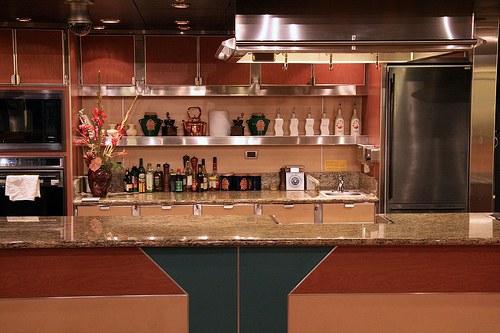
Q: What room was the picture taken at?
A: It was taken at the kitchen.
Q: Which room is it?
A: It is a kitchen.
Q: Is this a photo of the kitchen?
A: Yes, it is showing the kitchen.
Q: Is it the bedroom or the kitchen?
A: It is the kitchen.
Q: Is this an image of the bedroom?
A: No, the picture is showing the kitchen.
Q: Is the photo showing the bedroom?
A: No, the picture is showing the kitchen.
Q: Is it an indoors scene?
A: Yes, it is indoors.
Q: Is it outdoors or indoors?
A: It is indoors.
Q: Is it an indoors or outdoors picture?
A: It is indoors.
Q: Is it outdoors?
A: No, it is indoors.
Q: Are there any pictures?
A: No, there are no pictures.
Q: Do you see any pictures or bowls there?
A: No, there are no pictures or bowls.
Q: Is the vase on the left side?
A: Yes, the vase is on the left of the image.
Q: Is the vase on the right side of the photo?
A: No, the vase is on the left of the image.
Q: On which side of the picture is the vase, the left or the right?
A: The vase is on the left of the image.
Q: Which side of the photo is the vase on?
A: The vase is on the left of the image.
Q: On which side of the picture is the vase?
A: The vase is on the left of the image.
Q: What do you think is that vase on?
A: The vase is on the counter.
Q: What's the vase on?
A: The vase is on the counter.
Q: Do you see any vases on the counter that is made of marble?
A: Yes, there is a vase on the counter.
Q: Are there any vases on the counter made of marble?
A: Yes, there is a vase on the counter.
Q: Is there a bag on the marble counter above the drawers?
A: No, there is a vase on the counter.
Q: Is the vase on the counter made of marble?
A: Yes, the vase is on the counter.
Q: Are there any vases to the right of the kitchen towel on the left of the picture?
A: Yes, there is a vase to the right of the kitchen towel.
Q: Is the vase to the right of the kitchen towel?
A: Yes, the vase is to the right of the kitchen towel.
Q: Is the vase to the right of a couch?
A: No, the vase is to the right of the kitchen towel.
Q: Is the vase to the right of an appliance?
A: Yes, the vase is to the right of an appliance.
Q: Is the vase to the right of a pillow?
A: No, the vase is to the right of an appliance.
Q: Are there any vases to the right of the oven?
A: Yes, there is a vase to the right of the oven.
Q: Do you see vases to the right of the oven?
A: Yes, there is a vase to the right of the oven.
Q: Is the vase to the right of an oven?
A: Yes, the vase is to the right of an oven.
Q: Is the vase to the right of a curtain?
A: No, the vase is to the right of an oven.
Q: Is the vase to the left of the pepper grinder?
A: Yes, the vase is to the left of the pepper grinder.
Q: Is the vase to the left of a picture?
A: No, the vase is to the left of the pepper grinder.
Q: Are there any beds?
A: No, there are no beds.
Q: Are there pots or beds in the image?
A: No, there are no beds or pots.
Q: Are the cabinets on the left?
A: Yes, the cabinets are on the left of the image.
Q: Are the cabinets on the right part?
A: No, the cabinets are on the left of the image.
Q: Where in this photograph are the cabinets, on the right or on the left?
A: The cabinets are on the left of the image.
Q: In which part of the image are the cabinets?
A: The cabinets are on the left of the image.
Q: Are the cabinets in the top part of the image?
A: Yes, the cabinets are in the top of the image.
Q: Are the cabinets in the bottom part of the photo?
A: No, the cabinets are in the top of the image.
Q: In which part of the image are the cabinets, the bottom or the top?
A: The cabinets are in the top of the image.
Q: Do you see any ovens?
A: Yes, there is an oven.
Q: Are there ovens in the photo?
A: Yes, there is an oven.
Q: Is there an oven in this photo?
A: Yes, there is an oven.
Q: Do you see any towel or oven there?
A: Yes, there is an oven.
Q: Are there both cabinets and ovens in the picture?
A: Yes, there are both an oven and a cabinet.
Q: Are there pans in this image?
A: No, there are no pans.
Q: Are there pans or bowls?
A: No, there are no pans or bowls.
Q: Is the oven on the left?
A: Yes, the oven is on the left of the image.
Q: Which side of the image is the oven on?
A: The oven is on the left of the image.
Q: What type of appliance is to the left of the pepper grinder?
A: The appliance is an oven.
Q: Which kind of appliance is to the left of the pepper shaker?
A: The appliance is an oven.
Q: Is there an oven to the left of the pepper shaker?
A: Yes, there is an oven to the left of the pepper shaker.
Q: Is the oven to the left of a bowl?
A: No, the oven is to the left of the pepper grinder.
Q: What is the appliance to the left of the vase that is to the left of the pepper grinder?
A: The appliance is an oven.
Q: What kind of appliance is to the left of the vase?
A: The appliance is an oven.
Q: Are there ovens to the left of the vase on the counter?
A: Yes, there is an oven to the left of the vase.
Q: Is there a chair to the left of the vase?
A: No, there is an oven to the left of the vase.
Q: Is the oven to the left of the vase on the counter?
A: Yes, the oven is to the left of the vase.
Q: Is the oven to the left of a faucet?
A: No, the oven is to the left of the vase.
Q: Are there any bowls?
A: No, there are no bowls.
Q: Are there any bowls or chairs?
A: No, there are no bowls or chairs.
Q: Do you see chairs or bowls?
A: No, there are no bowls or chairs.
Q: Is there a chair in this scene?
A: No, there are no chairs.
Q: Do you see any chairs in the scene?
A: No, there are no chairs.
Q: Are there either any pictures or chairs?
A: No, there are no chairs or pictures.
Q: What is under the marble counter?
A: The drawers are under the counter.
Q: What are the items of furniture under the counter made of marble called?
A: The pieces of furniture are drawers.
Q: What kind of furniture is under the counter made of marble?
A: The pieces of furniture are drawers.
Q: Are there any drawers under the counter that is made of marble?
A: Yes, there are drawers under the counter.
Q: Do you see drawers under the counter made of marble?
A: Yes, there are drawers under the counter.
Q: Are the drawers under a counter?
A: Yes, the drawers are under a counter.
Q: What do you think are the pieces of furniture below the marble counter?
A: The pieces of furniture are drawers.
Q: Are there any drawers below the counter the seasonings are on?
A: Yes, there are drawers below the counter.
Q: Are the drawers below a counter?
A: Yes, the drawers are below a counter.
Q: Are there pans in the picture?
A: No, there are no pans.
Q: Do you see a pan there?
A: No, there are no pans.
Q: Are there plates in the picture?
A: No, there are no plates.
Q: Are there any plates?
A: No, there are no plates.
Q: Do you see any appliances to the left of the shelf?
A: Yes, there is an appliance to the left of the shelf.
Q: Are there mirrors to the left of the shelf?
A: No, there is an appliance to the left of the shelf.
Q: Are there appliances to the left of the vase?
A: Yes, there is an appliance to the left of the vase.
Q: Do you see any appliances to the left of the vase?
A: Yes, there is an appliance to the left of the vase.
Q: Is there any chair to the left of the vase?
A: No, there is an appliance to the left of the vase.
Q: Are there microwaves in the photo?
A: Yes, there is a microwave.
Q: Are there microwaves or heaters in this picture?
A: Yes, there is a microwave.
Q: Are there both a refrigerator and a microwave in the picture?
A: Yes, there are both a microwave and a refrigerator.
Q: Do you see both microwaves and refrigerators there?
A: Yes, there are both a microwave and a refrigerator.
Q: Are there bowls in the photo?
A: No, there are no bowls.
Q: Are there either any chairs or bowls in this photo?
A: No, there are no bowls or chairs.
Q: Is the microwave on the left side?
A: Yes, the microwave is on the left of the image.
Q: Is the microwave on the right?
A: No, the microwave is on the left of the image.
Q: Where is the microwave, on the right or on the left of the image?
A: The microwave is on the left of the image.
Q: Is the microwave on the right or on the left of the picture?
A: The microwave is on the left of the image.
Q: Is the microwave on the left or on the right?
A: The microwave is on the left of the image.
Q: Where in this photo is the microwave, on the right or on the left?
A: The microwave is on the left of the image.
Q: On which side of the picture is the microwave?
A: The microwave is on the left of the image.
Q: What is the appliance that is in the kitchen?
A: The appliance is a microwave.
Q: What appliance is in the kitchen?
A: The appliance is a microwave.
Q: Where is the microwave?
A: The microwave is in the kitchen.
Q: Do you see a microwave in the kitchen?
A: Yes, there is a microwave in the kitchen.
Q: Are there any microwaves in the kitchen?
A: Yes, there is a microwave in the kitchen.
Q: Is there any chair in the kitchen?
A: No, there is a microwave in the kitchen.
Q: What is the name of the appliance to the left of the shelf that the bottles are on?
A: The appliance is a microwave.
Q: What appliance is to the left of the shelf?
A: The appliance is a microwave.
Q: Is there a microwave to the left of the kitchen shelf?
A: Yes, there is a microwave to the left of the shelf.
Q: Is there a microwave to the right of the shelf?
A: No, the microwave is to the left of the shelf.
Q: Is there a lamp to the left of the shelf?
A: No, there is a microwave to the left of the shelf.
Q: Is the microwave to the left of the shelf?
A: Yes, the microwave is to the left of the shelf.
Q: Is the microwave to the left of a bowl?
A: No, the microwave is to the left of the shelf.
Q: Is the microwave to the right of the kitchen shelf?
A: No, the microwave is to the left of the shelf.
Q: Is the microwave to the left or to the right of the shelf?
A: The microwave is to the left of the shelf.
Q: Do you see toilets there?
A: No, there are no toilets.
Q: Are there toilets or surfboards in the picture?
A: No, there are no toilets or surfboards.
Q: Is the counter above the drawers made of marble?
A: Yes, the counter is made of marble.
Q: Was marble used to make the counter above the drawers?
A: Yes, the counter is made of marble.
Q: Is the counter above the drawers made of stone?
A: No, the counter is made of marble.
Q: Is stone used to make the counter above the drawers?
A: No, the counter is made of marble.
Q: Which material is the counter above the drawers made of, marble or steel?
A: The counter is made of marble.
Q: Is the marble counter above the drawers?
A: Yes, the counter is above the drawers.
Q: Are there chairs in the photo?
A: No, there are no chairs.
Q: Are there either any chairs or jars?
A: No, there are no chairs or jars.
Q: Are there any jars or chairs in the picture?
A: No, there are no chairs or jars.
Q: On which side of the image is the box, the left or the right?
A: The box is on the right of the image.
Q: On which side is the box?
A: The box is on the right of the image.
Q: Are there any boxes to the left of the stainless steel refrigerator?
A: Yes, there is a box to the left of the fridge.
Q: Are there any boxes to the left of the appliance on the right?
A: Yes, there is a box to the left of the fridge.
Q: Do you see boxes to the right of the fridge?
A: No, the box is to the left of the fridge.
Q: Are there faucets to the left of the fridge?
A: No, there is a box to the left of the fridge.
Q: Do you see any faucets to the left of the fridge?
A: No, there is a box to the left of the fridge.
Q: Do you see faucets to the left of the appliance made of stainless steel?
A: No, there is a box to the left of the fridge.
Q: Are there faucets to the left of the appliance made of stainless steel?
A: No, there is a box to the left of the fridge.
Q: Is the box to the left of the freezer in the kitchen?
A: Yes, the box is to the left of the freezer.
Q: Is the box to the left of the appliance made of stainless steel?
A: Yes, the box is to the left of the freezer.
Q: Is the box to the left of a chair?
A: No, the box is to the left of the freezer.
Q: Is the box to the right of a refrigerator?
A: No, the box is to the left of a refrigerator.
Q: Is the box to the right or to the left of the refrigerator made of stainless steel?
A: The box is to the left of the freezer.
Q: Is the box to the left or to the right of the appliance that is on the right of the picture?
A: The box is to the left of the freezer.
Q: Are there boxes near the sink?
A: Yes, there is a box near the sink.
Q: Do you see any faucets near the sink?
A: No, there is a box near the sink.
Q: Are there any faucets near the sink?
A: No, there is a box near the sink.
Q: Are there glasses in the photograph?
A: No, there are no glasses.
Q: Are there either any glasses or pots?
A: No, there are no glasses or pots.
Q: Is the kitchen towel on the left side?
A: Yes, the kitchen towel is on the left of the image.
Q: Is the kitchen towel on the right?
A: No, the kitchen towel is on the left of the image.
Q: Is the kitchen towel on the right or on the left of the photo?
A: The kitchen towel is on the left of the image.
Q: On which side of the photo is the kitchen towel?
A: The kitchen towel is on the left of the image.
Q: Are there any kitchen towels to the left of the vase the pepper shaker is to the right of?
A: Yes, there is a kitchen towel to the left of the vase.